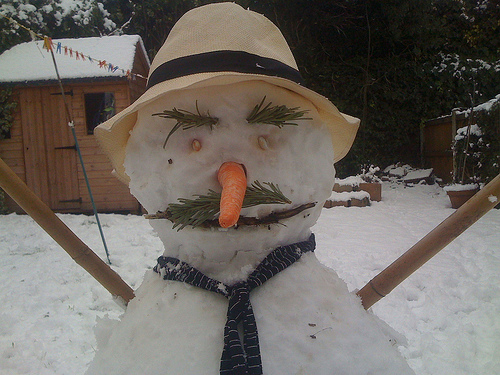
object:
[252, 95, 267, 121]
pine needles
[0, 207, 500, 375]
ground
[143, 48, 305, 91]
band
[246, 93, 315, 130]
eyebrow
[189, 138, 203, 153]
eye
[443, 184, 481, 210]
pot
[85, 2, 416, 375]
snowman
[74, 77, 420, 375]
snow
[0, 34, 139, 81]
snow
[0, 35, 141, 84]
roof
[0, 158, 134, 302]
stick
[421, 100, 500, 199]
fence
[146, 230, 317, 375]
tie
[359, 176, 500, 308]
wooden pole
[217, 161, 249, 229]
carrot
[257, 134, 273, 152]
eye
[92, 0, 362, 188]
hat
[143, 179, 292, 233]
moustache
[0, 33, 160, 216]
building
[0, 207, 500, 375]
snow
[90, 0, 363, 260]
snowman's head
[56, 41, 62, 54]
clothespins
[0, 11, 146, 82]
laundry line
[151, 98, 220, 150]
eyebrow